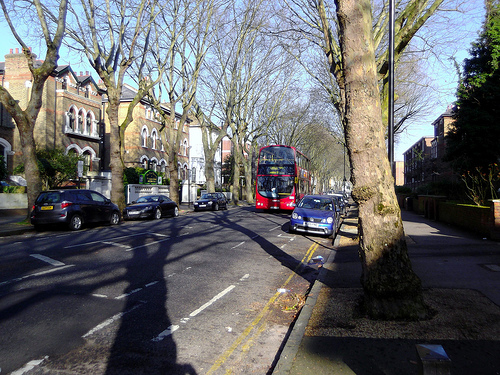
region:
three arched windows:
[58, 110, 111, 135]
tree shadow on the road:
[101, 224, 223, 373]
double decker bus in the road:
[255, 138, 322, 213]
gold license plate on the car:
[28, 197, 70, 218]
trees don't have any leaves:
[64, 8, 296, 97]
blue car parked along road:
[292, 195, 363, 250]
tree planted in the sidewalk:
[338, 229, 464, 345]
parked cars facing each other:
[27, 183, 192, 232]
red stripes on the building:
[0, 63, 39, 79]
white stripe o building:
[209, 138, 265, 155]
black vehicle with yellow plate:
[17, 182, 135, 233]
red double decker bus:
[254, 127, 321, 219]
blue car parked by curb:
[273, 177, 364, 249]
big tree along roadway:
[46, 56, 171, 221]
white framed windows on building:
[39, 59, 124, 198]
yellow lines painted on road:
[224, 259, 305, 349]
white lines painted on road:
[109, 241, 231, 352]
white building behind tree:
[174, 91, 244, 198]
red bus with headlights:
[233, 135, 300, 237]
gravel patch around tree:
[316, 279, 494, 364]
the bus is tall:
[210, 139, 386, 314]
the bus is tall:
[240, 111, 313, 240]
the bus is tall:
[295, 155, 376, 257]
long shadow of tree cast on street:
[102, 196, 202, 372]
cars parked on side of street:
[28, 184, 238, 239]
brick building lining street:
[18, 100, 263, 205]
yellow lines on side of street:
[210, 217, 335, 372]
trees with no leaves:
[120, 12, 345, 163]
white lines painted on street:
[62, 202, 228, 342]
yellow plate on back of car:
[30, 196, 69, 216]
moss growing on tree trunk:
[352, 182, 399, 219]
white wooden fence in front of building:
[112, 178, 205, 205]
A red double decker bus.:
[252, 143, 312, 210]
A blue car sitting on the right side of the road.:
[288, 192, 345, 242]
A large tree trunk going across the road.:
[102, 225, 195, 374]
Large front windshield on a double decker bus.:
[252, 171, 296, 196]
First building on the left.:
[2, 44, 111, 203]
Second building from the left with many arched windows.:
[92, 74, 189, 215]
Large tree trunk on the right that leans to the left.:
[335, 29, 435, 323]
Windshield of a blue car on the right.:
[297, 196, 332, 209]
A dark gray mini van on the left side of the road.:
[29, 188, 121, 228]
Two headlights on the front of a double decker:
[252, 200, 293, 207]